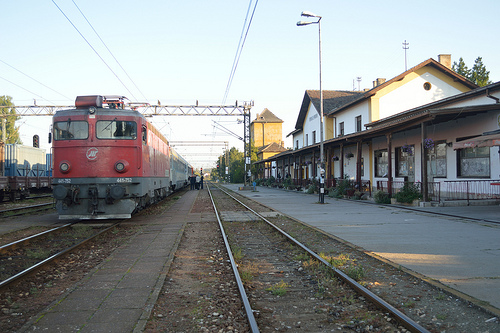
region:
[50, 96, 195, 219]
red train on tracks is stopped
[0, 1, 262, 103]
power lines above train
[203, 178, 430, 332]
tracks on right are empty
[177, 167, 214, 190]
group of people are waiting for train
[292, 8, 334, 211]
light pole is next to station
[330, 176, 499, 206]
railing is in front of building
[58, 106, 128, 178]
headlights are on front of train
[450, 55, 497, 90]
green trees behind building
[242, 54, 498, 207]
building are on side of platform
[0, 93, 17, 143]
green tree is behind train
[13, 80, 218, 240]
a red engine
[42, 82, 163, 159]
front windows on a train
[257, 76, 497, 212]
buildings along a train track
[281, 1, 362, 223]
lighting on a tall pole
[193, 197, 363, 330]
train tracks with grass and rocks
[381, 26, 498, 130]
roof of a building and chimney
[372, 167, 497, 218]
metal railing by a building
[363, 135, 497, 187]
windows on a building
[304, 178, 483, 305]
paved area along side the train tracks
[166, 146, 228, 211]
people standing near the train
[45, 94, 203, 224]
Red train on the tracks.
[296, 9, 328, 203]
Light pole with two lights on the top.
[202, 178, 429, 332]
Train track to the right of a red train.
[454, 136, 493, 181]
First large window on the right.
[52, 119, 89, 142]
Front left windshield of a red train.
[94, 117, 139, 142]
Right side front train window.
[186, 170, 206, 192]
Group of people to the right of a red train.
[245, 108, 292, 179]
Pointy roof on a tan colored building.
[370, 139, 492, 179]
Four large windows on the building to the right.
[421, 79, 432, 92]
Small round window on the side of the building.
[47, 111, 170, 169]
the train is red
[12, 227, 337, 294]
there are four tracks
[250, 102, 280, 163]
the building is yellow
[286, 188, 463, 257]
there is a platform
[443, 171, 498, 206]
a fence is on the left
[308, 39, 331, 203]
there is tall pole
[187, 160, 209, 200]
passengers boarding the train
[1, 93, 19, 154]
there are green trees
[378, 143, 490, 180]
there are four windows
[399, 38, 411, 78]
a antenna is on top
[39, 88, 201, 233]
train on a pair of tracks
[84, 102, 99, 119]
headlight on a train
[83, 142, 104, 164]
logo on the front of a train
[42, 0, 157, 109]
overhead power lines for a train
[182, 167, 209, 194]
people standing near a train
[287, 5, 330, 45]
lights on a pole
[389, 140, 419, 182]
window on a building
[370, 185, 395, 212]
green plant near a building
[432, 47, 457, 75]
chimney on a building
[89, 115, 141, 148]
front windshield on a train